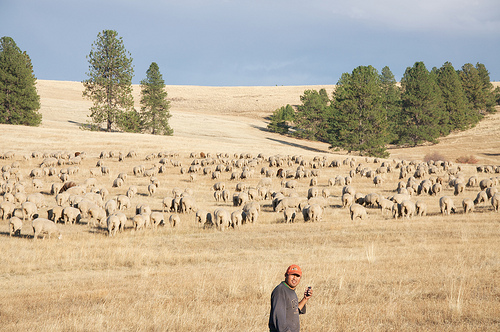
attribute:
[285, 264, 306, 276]
hat — orange, cap, red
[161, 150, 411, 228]
sheep — grazing, feeding, many, hungry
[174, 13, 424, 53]
sky — blue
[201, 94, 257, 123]
grass — brown, yellow, dry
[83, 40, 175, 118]
trees — grouped, green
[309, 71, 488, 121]
trees — grouped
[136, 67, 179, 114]
tree — evergreen, green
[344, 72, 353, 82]
leaves — green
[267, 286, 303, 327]
shirt — blue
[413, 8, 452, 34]
cloud — white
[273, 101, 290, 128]
shrubs — small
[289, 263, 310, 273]
cap — orange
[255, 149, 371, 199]
flock — brown, feeding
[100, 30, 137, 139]
tree — tall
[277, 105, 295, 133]
bushhes — little